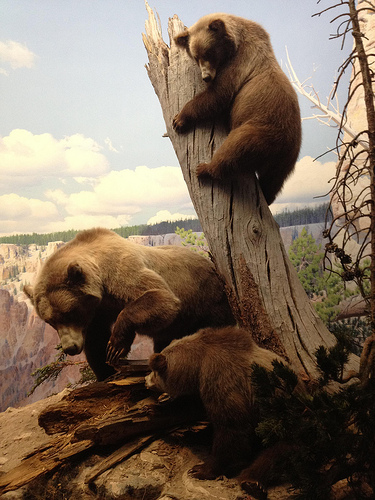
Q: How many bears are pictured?
A: Three.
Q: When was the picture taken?
A: During the day.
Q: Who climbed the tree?
A: The bear.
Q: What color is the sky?
A: Blue.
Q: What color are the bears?
A: Brown.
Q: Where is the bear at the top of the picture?
A: Up a tree.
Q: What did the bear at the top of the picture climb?
A: A tree.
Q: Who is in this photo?
A: Three bears.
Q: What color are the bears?
A: Brown.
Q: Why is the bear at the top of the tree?
A: He is climbing it.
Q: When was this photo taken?
A: During the day.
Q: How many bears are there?
A: Three.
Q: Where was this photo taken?
A: Outside near the tree.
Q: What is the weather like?
A: Sunny.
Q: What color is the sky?
A: Blue.